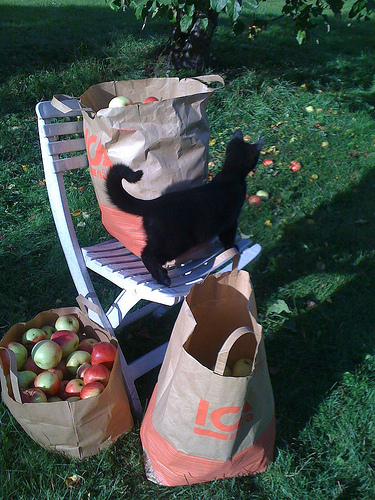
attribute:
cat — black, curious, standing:
[105, 130, 261, 282]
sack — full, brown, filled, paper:
[0, 297, 132, 462]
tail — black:
[105, 165, 152, 217]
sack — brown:
[136, 247, 278, 487]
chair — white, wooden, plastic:
[37, 96, 263, 421]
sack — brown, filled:
[50, 71, 226, 271]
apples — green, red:
[8, 312, 111, 404]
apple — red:
[90, 341, 112, 369]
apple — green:
[29, 338, 65, 371]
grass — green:
[3, 5, 374, 499]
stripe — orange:
[139, 443, 279, 487]